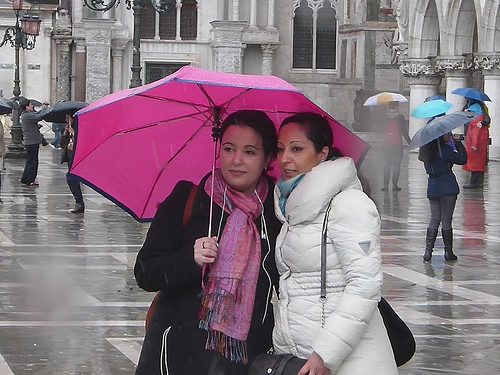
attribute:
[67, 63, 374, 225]
umbrella — pink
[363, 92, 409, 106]
umbrella — white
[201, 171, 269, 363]
scarf — pink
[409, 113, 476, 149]
umbrella — blue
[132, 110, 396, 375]
women — standing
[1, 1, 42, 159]
lamp — decorative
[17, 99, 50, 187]
man — standing, photoing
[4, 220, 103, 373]
sidewalk — rainy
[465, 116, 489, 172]
raincoat — red